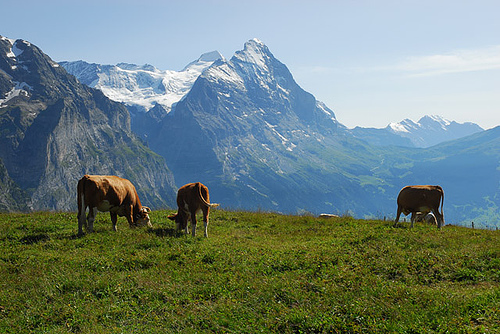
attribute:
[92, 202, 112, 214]
udder — cow's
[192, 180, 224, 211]
tail — wagging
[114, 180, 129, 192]
fur — brown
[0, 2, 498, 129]
sky — blue, clouded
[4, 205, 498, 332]
hill — grassy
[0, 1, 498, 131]
clouds — white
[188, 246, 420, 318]
grass — green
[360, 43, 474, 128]
cloud — flat, small